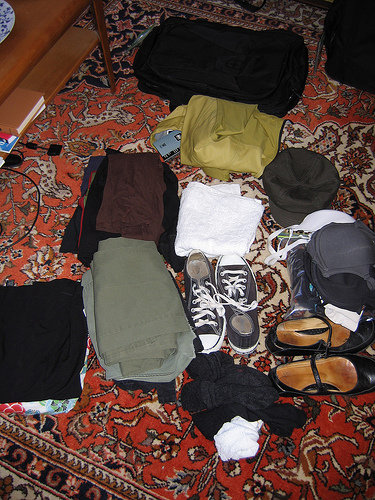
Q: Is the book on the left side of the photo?
A: Yes, the book is on the left of the image.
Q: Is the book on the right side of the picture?
A: No, the book is on the left of the image.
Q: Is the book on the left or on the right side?
A: The book is on the left of the image.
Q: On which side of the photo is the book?
A: The book is on the left of the image.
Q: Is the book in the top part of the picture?
A: Yes, the book is in the top of the image.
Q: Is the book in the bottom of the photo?
A: No, the book is in the top of the image.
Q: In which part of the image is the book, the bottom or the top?
A: The book is in the top of the image.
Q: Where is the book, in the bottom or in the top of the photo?
A: The book is in the top of the image.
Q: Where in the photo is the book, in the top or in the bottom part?
A: The book is in the top of the image.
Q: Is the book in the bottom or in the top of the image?
A: The book is in the top of the image.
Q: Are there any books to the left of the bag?
A: Yes, there is a book to the left of the bag.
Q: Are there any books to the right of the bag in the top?
A: No, the book is to the left of the bag.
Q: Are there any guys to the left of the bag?
A: No, there is a book to the left of the bag.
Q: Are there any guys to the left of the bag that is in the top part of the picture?
A: No, there is a book to the left of the bag.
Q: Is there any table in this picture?
A: Yes, there is a table.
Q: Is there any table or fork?
A: Yes, there is a table.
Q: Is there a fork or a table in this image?
A: Yes, there is a table.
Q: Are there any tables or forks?
A: Yes, there is a table.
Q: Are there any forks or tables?
A: Yes, there is a table.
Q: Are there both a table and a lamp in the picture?
A: No, there is a table but no lamps.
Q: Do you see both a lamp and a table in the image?
A: No, there is a table but no lamps.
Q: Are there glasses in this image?
A: No, there are no glasses.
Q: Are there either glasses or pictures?
A: No, there are no glasses or pictures.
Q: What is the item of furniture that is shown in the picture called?
A: The piece of furniture is a table.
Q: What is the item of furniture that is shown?
A: The piece of furniture is a table.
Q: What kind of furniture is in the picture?
A: The furniture is a table.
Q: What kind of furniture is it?
A: The piece of furniture is a table.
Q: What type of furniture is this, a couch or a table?
A: That is a table.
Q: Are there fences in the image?
A: No, there are no fences.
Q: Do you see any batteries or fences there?
A: No, there are no fences or batteries.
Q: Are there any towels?
A: Yes, there is a towel.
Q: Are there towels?
A: Yes, there is a towel.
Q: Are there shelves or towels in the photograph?
A: Yes, there is a towel.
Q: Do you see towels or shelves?
A: Yes, there is a towel.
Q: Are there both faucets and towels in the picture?
A: No, there is a towel but no faucets.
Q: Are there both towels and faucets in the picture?
A: No, there is a towel but no faucets.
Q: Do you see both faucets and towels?
A: No, there is a towel but no faucets.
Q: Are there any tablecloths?
A: No, there are no tablecloths.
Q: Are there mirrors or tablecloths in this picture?
A: No, there are no tablecloths or mirrors.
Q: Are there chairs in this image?
A: No, there are no chairs.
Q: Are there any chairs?
A: No, there are no chairs.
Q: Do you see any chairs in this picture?
A: No, there are no chairs.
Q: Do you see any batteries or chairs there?
A: No, there are no chairs or batteries.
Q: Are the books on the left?
A: Yes, the books are on the left of the image.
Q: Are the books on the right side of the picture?
A: No, the books are on the left of the image.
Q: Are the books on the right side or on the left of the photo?
A: The books are on the left of the image.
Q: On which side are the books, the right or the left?
A: The books are on the left of the image.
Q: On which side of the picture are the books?
A: The books are on the left of the image.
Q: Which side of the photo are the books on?
A: The books are on the left of the image.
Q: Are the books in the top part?
A: Yes, the books are in the top of the image.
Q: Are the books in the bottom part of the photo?
A: No, the books are in the top of the image.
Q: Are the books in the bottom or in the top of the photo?
A: The books are in the top of the image.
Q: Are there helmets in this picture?
A: No, there are no helmets.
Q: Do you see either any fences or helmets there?
A: No, there are no helmets or fences.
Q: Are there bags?
A: Yes, there is a bag.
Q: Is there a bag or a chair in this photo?
A: Yes, there is a bag.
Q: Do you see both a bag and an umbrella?
A: No, there is a bag but no umbrellas.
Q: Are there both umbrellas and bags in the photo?
A: No, there is a bag but no umbrellas.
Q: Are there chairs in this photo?
A: No, there are no chairs.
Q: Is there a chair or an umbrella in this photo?
A: No, there are no chairs or umbrellas.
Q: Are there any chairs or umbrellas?
A: No, there are no chairs or umbrellas.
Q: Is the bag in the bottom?
A: No, the bag is in the top of the image.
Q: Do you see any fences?
A: No, there are no fences.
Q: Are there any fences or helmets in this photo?
A: No, there are no fences or helmets.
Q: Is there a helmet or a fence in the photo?
A: No, there are no fences or helmets.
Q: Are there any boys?
A: No, there are no boys.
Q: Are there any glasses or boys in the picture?
A: No, there are no boys or glasses.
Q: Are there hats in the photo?
A: Yes, there is a hat.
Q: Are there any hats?
A: Yes, there is a hat.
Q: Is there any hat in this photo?
A: Yes, there is a hat.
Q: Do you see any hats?
A: Yes, there is a hat.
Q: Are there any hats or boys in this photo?
A: Yes, there is a hat.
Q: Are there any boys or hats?
A: Yes, there is a hat.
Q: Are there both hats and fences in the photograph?
A: No, there is a hat but no fences.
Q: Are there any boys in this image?
A: No, there are no boys.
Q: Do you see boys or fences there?
A: No, there are no boys or fences.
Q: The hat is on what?
A: The hat is on the rug.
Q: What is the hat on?
A: The hat is on the rug.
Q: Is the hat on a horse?
A: No, the hat is on a rug.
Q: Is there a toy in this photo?
A: No, there are no toys.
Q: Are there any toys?
A: No, there are no toys.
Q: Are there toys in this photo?
A: No, there are no toys.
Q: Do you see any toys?
A: No, there are no toys.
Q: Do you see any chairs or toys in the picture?
A: No, there are no toys or chairs.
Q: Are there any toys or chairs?
A: No, there are no toys or chairs.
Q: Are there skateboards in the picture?
A: No, there are no skateboards.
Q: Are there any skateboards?
A: No, there are no skateboards.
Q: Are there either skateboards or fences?
A: No, there are no skateboards or fences.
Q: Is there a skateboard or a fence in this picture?
A: No, there are no skateboards or fences.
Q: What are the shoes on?
A: The shoes are on the rug.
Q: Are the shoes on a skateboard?
A: No, the shoes are on the rug.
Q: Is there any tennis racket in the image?
A: No, there are no rackets.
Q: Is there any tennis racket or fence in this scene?
A: No, there are no rackets or fences.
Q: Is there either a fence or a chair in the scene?
A: No, there are no chairs or fences.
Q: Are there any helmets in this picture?
A: No, there are no helmets.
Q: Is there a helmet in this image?
A: No, there are no helmets.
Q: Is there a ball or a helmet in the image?
A: No, there are no helmets or balls.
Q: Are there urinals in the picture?
A: No, there are no urinals.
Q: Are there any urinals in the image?
A: No, there are no urinals.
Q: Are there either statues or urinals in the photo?
A: No, there are no urinals or statues.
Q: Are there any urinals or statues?
A: No, there are no urinals or statues.